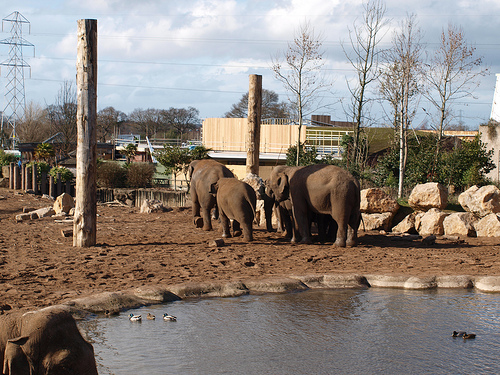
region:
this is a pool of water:
[235, 290, 419, 367]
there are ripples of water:
[268, 307, 395, 369]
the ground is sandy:
[8, 250, 79, 296]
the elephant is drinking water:
[3, 308, 101, 373]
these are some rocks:
[381, 185, 498, 233]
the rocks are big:
[411, 187, 498, 239]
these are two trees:
[398, 2, 470, 186]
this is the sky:
[143, 20, 248, 47]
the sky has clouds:
[172, 7, 334, 31]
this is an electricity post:
[5, 6, 31, 152]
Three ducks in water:
[121, 305, 197, 331]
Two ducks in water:
[433, 313, 498, 346]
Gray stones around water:
[87, 281, 266, 317]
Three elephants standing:
[184, 146, 376, 256]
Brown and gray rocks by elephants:
[360, 184, 488, 251]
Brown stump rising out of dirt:
[58, 29, 139, 269]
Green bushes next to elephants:
[315, 121, 498, 198]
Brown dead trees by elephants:
[290, 11, 446, 201]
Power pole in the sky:
[3, 15, 80, 170]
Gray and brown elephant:
[267, 162, 376, 267]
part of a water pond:
[306, 302, 423, 361]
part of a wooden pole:
[76, 81, 98, 233]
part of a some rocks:
[395, 177, 471, 238]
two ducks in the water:
[440, 322, 475, 345]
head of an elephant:
[33, 317, 86, 360]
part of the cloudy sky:
[145, 4, 202, 78]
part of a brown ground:
[131, 230, 208, 277]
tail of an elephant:
[241, 202, 266, 224]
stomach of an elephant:
[308, 182, 329, 217]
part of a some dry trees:
[328, 0, 418, 160]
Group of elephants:
[0, 1, 45, 133]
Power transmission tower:
[0, 2, 40, 144]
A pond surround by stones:
[30, 261, 495, 371]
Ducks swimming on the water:
[121, 303, 208, 328]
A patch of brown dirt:
[420, 235, 496, 267]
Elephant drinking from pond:
[1, 280, 121, 371]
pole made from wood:
[60, 6, 106, 262]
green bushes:
[363, 130, 490, 183]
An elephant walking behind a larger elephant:
[170, 126, 261, 246]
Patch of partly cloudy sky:
[108, 7, 305, 82]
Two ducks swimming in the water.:
[408, 319, 482, 349]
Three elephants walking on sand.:
[122, 140, 354, 250]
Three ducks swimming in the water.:
[105, 300, 191, 333]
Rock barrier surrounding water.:
[120, 260, 472, 307]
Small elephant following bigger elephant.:
[174, 164, 263, 226]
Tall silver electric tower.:
[0, 35, 62, 142]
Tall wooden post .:
[230, 60, 280, 192]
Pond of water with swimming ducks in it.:
[152, 268, 471, 372]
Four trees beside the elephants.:
[286, 12, 482, 219]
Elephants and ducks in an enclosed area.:
[20, 5, 499, 368]